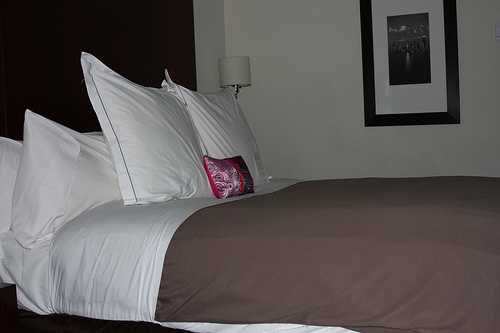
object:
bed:
[3, 48, 498, 331]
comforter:
[186, 176, 486, 330]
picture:
[359, 0, 459, 118]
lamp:
[206, 55, 258, 107]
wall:
[221, 1, 499, 183]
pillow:
[198, 152, 254, 201]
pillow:
[161, 70, 266, 183]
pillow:
[79, 49, 215, 210]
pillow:
[9, 107, 126, 246]